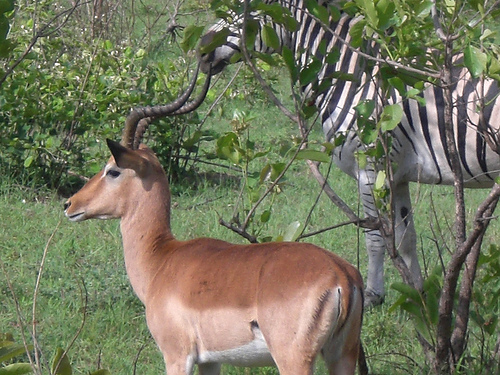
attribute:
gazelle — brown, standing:
[46, 74, 361, 366]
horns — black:
[131, 68, 218, 133]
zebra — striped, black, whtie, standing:
[210, 9, 482, 231]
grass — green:
[22, 299, 94, 336]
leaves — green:
[47, 37, 90, 96]